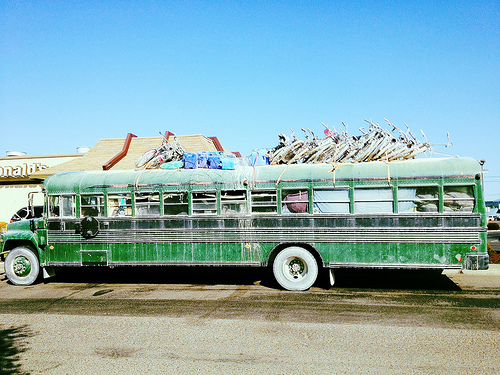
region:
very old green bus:
[5, 155, 498, 269]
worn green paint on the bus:
[113, 220, 233, 267]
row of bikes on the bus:
[262, 124, 432, 167]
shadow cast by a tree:
[0, 319, 47, 370]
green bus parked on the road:
[11, 128, 498, 334]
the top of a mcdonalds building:
[4, 130, 220, 220]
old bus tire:
[269, 246, 316, 294]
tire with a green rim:
[3, 247, 38, 286]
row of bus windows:
[48, 194, 481, 220]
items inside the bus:
[281, 187, 477, 224]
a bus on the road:
[28, 93, 488, 358]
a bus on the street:
[117, 115, 443, 362]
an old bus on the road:
[152, 122, 452, 367]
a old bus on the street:
[93, 122, 468, 374]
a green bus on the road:
[89, 132, 401, 329]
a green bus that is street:
[83, 122, 399, 325]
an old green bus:
[36, 94, 480, 372]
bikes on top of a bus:
[129, 111, 445, 248]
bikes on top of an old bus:
[197, 69, 477, 236]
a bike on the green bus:
[267, 131, 476, 257]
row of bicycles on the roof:
[268, 120, 431, 165]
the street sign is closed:
[78, 217, 100, 235]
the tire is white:
[271, 248, 316, 292]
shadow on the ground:
[1, 321, 32, 372]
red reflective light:
[470, 245, 475, 250]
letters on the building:
[0, 163, 45, 176]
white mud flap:
[328, 270, 336, 285]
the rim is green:
[13, 255, 30, 275]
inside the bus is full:
[106, 190, 476, 212]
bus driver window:
[49, 197, 74, 219]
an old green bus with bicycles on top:
[5, 120, 497, 302]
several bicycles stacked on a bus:
[152, 126, 453, 171]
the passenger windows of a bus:
[83, 184, 468, 213]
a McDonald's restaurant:
[3, 158, 53, 205]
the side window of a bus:
[19, 185, 39, 224]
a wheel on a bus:
[265, 243, 320, 293]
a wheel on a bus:
[6, 245, 42, 288]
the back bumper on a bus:
[458, 242, 490, 272]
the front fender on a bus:
[0, 224, 41, 249]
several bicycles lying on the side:
[272, 125, 432, 163]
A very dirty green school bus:
[5, 158, 487, 295]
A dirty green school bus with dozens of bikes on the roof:
[2, 124, 498, 301]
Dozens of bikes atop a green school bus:
[264, 116, 456, 293]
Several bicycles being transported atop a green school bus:
[258, 117, 459, 288]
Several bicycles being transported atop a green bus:
[264, 113, 450, 300]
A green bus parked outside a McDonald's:
[2, 132, 494, 304]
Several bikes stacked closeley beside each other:
[263, 119, 442, 161]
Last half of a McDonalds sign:
[3, 152, 66, 179]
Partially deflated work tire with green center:
[4, 248, 37, 287]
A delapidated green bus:
[0, 170, 492, 297]